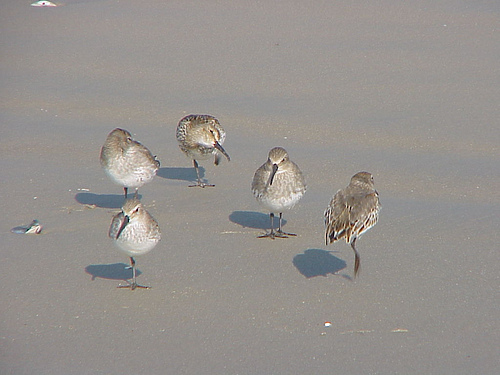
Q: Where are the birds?
A: The birds are on the shoreline.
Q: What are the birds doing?
A: The birds are standing on the sand.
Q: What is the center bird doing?
A: The center bird is scratching its eye.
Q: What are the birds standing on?
A: Sand.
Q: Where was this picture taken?
A: On a beach.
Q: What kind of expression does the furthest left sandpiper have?
A: Cynical.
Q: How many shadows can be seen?
A: Five.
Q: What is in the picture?
A: A group of birds of the same family.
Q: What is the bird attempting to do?
A: Fly.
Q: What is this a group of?
A: Birds.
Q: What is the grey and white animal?
A: A bird.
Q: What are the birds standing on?
A: Sand.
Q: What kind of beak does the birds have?
A: Long and pointy.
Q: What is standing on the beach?
A: Some birds.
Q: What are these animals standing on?
A: Ground.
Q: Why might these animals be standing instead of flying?
A: They're resting.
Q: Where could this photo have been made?
A: Seashore.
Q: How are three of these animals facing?
A: Toward camera.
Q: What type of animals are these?
A: Birds.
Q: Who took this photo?
A: Photographer.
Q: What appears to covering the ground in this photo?
A: Sand.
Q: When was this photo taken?
A: Daytime.